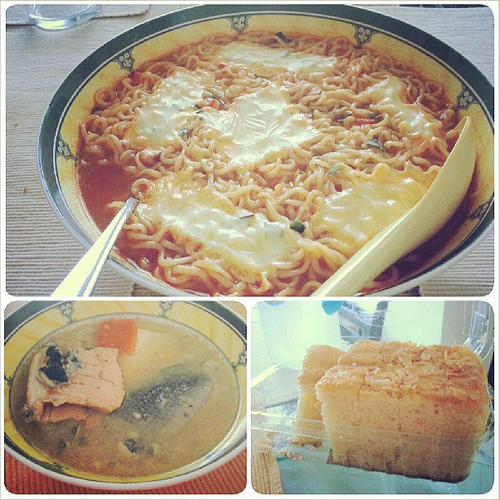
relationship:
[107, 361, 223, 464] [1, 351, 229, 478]
fish in bowl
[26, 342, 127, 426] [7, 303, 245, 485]
fish in bowl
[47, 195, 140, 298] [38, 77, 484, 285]
metal spoon in bowl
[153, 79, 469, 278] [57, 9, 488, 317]
soup in bowl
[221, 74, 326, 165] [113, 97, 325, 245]
cheese on soup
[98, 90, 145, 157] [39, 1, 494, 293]
noodles in bowl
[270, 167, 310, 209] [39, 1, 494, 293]
noodles in bowl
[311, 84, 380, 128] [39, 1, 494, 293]
noodles in bowl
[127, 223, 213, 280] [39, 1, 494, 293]
noodles in bowl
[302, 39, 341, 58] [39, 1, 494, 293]
noodles in bowl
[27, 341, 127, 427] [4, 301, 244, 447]
meat in bowl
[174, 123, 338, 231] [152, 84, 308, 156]
noodles and cheese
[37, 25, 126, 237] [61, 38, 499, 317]
rim of bowl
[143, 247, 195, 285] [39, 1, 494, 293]
noodles in bowl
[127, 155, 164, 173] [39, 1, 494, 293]
noodles in bowl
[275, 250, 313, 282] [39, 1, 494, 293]
noodles in bowl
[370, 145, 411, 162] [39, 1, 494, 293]
noodles in bowl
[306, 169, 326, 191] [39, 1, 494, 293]
noodles in bowl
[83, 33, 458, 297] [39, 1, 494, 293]
noodles in bowl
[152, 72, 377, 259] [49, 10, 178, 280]
noodles in bowl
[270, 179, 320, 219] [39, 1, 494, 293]
noodles in bowl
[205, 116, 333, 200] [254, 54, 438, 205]
cheese on noodles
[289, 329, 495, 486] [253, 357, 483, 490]
pastry in container